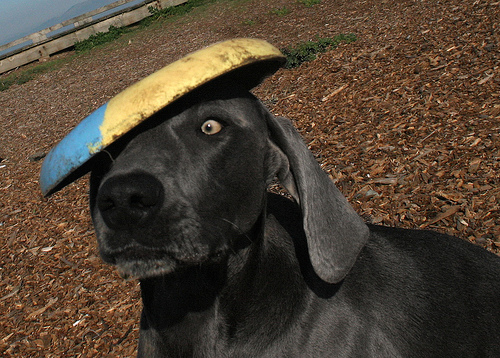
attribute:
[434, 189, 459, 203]
wood chip — small, brown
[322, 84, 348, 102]
wood chip — brown, small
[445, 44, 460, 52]
wood chip — small, brown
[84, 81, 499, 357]
dog — black, surprised, funny, shiny, dark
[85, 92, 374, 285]
head — black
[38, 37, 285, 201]
frisbee — blue, yellow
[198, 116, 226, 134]
eye — yellowish, wide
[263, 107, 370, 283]
ear — long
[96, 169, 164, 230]
nose — black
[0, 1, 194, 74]
railing — concrete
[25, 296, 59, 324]
wood chip — brown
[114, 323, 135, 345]
wood chip — brown